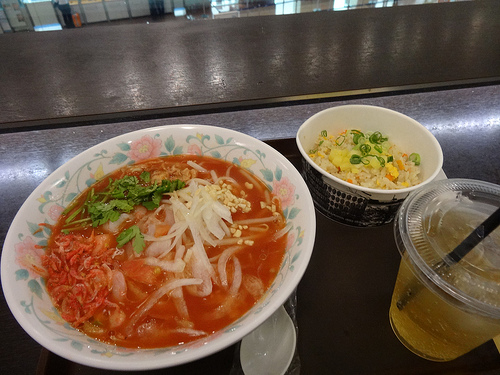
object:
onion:
[149, 183, 234, 246]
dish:
[0, 123, 316, 371]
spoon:
[240, 304, 297, 374]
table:
[0, 0, 500, 373]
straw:
[396, 207, 500, 310]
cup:
[389, 179, 500, 363]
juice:
[389, 211, 500, 360]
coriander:
[61, 171, 185, 254]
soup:
[47, 155, 288, 349]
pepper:
[350, 154, 361, 164]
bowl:
[296, 104, 443, 227]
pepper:
[335, 135, 345, 146]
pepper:
[369, 131, 387, 144]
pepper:
[409, 153, 420, 166]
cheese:
[205, 183, 251, 213]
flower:
[127, 134, 162, 162]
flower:
[271, 176, 296, 208]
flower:
[14, 236, 48, 278]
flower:
[48, 204, 64, 221]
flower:
[38, 307, 65, 325]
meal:
[0, 102, 500, 375]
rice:
[309, 129, 422, 190]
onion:
[169, 192, 219, 292]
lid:
[393, 178, 500, 319]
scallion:
[360, 144, 371, 156]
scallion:
[387, 155, 393, 163]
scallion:
[352, 137, 366, 150]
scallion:
[318, 140, 324, 146]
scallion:
[377, 157, 385, 167]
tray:
[0, 76, 500, 375]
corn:
[329, 149, 351, 170]